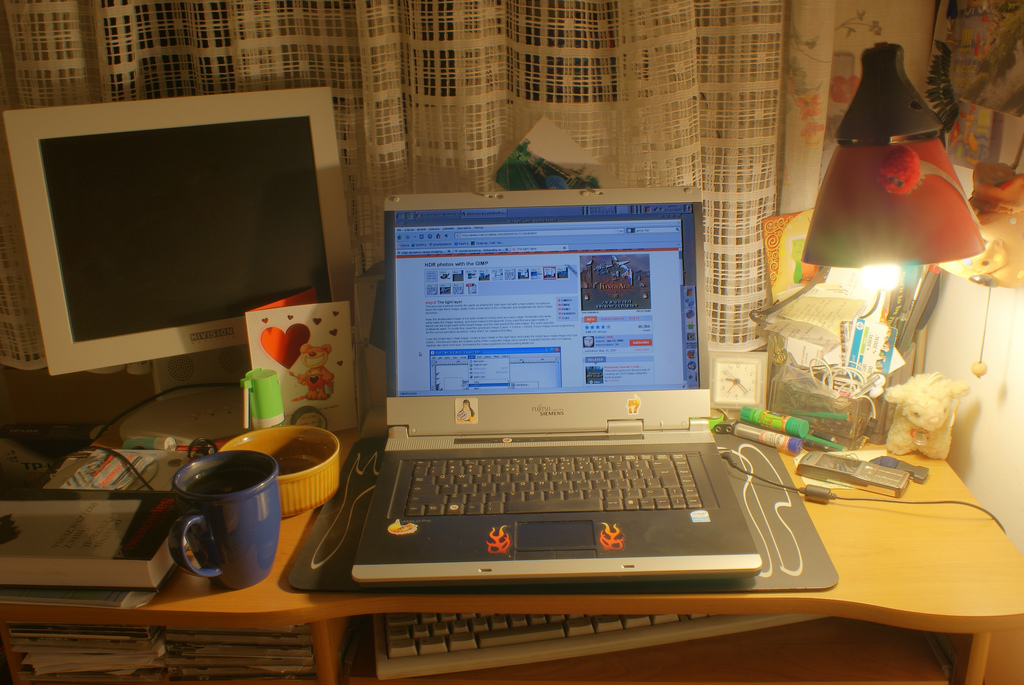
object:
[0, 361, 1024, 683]
desk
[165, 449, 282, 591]
mug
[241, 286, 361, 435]
card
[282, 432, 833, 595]
play mat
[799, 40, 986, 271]
lamp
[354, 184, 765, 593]
laptop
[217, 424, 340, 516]
bowl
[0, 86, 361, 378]
computer frame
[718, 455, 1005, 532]
computer cable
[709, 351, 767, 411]
white clock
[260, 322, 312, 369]
heart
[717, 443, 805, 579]
pictures